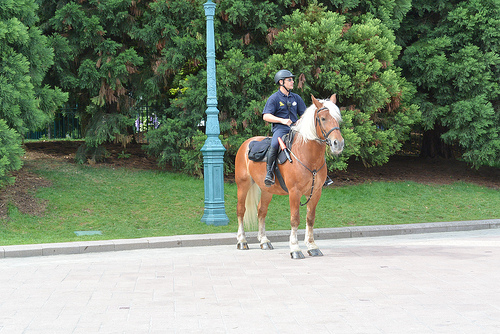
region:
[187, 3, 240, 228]
Blue pole behind horse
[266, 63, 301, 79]
Black helmet on man's head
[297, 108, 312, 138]
White mane on horse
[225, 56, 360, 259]
Officer on top of horse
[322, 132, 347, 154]
Horse has grey nose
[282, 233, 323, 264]
Front feet of horse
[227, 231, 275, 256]
Back feet of horse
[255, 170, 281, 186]
Man wears black boots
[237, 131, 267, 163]
Black harnest on horse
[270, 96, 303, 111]
Man wears blue shirt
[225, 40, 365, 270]
police officer on horse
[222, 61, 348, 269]
patrol officer on horse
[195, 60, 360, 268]
cop on horseback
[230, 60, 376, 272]
cop patrolling on horseback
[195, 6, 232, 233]
gray light pole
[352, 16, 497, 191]
healthy green pinetrees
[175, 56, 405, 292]
Police officer patrolling park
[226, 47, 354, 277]
police officer keeping watch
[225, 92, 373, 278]
brown horse with white mane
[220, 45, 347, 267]
Mounted police vehicle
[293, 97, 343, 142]
the horse's white hair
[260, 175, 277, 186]
the foot of the man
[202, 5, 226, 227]
a tall green pole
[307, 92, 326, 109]
a horse's ear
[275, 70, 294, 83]
a dark helmet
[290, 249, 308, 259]
a horse's hoof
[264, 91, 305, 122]
a short sleeve blue shirt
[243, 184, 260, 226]
the tail of the horse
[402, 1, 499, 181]
a big green tree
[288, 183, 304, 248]
the leg of a horse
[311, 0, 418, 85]
green and brown trees.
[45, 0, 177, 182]
beautiful dark green and brown trees.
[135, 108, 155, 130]
a black fence is behind the trees.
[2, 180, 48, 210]
dirt is in the grass.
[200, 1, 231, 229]
a long green pole is on the grass.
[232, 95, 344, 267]
a brown and white horse.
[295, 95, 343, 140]
the horse has white hair.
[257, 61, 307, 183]
police officer is on top of the horse.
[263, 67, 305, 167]
the officer is wearing a blue suit.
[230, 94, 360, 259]
a horse is standing in the street.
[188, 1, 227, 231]
A light post.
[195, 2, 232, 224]
The light post is green.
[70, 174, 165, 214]
The grass is green.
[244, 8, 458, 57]
The trees are green.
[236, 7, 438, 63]
The trees have leaves.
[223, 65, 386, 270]
A person on a horse.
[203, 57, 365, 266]
The horse is brown and white.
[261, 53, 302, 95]
The person is wearing a helmet.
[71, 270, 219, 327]
The road is gray.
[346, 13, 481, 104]
The tree leaves are green.